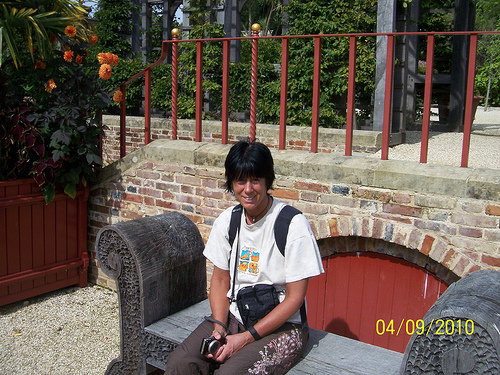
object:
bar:
[278, 36, 287, 151]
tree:
[257, 0, 378, 127]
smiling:
[239, 191, 259, 201]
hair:
[222, 141, 275, 193]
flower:
[61, 50, 73, 62]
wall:
[471, 228, 500, 260]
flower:
[35, 61, 46, 69]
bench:
[90, 211, 499, 375]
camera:
[200, 337, 224, 355]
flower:
[43, 78, 55, 93]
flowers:
[90, 32, 102, 46]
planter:
[1, 175, 88, 305]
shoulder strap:
[274, 203, 303, 257]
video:
[0, 0, 499, 375]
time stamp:
[373, 312, 477, 338]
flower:
[96, 53, 107, 63]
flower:
[105, 52, 112, 63]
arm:
[209, 215, 232, 308]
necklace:
[239, 200, 270, 222]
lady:
[161, 137, 330, 374]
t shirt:
[200, 195, 325, 324]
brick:
[304, 162, 341, 189]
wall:
[303, 194, 334, 219]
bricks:
[394, 193, 463, 225]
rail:
[112, 27, 494, 162]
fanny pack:
[234, 282, 282, 334]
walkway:
[372, 103, 500, 166]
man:
[168, 141, 328, 374]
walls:
[132, 179, 163, 202]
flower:
[98, 64, 111, 79]